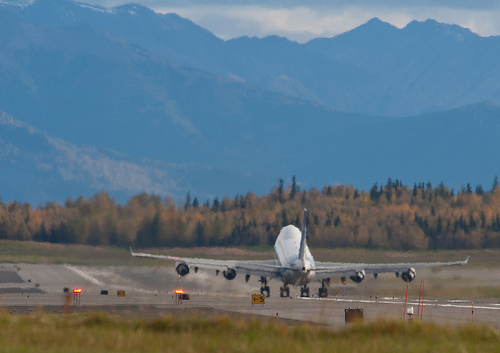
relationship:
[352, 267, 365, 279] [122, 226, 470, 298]
jet engine on plane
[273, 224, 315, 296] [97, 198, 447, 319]
jet engine on a plane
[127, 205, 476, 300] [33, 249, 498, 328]
airplane on runway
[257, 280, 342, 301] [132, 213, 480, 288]
wheels of airplane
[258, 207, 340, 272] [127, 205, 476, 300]
tail of airplane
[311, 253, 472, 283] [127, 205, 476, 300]
wing of airplane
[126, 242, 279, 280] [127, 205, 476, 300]
wing of airplane